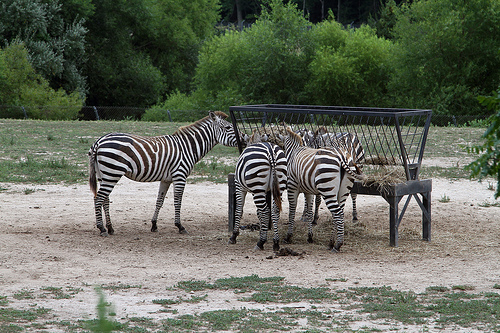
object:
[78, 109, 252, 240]
zebra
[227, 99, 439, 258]
trough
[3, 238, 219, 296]
ground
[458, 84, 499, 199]
leaves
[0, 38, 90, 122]
tree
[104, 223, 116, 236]
hoof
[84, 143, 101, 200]
tail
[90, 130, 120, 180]
behind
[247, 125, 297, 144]
hay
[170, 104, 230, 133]
mane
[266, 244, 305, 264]
feces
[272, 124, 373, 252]
zebra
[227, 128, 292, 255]
zebra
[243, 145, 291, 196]
butt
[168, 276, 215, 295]
grass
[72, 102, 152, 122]
fence